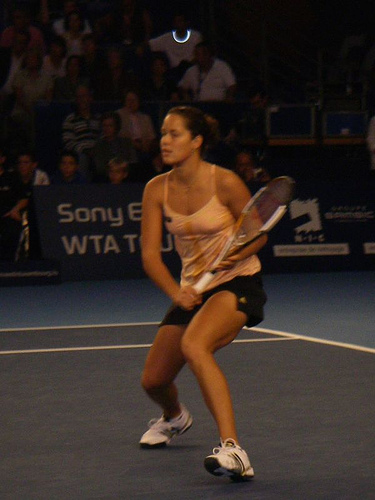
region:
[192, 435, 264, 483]
white shoe on tennis player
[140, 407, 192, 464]
white shoe on tennis player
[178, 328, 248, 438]
left leg of tennis player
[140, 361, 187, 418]
right leg of tennis player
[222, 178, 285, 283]
tennis racquet in player's hand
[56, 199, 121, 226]
sony advertisement on wall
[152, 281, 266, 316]
black tennis skirt on woman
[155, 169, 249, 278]
peach tank top on woman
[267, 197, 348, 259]
logo of sponsor on wall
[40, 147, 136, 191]
spectators in stand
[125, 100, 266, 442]
this is a tennis player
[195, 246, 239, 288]
she is holding a racket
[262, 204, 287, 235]
the racket is white in color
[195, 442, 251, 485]
the leg is raised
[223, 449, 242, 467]
the shoe is white in color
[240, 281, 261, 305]
the skirt is black in color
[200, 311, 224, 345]
this is the thigh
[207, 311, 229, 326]
the player is light skinned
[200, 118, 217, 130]
the hair is short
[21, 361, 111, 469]
the pitch is tarmacked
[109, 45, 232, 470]
a woman playing tennis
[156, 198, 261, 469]
a woman playing tennis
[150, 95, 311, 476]
a woman playing tennis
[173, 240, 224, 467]
a woman playing tennis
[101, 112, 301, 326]
woman playing a game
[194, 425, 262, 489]
shoe of the lady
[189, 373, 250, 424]
leg of the lady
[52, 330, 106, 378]
white line on court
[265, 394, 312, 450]
dark blue court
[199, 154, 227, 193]
strap on the woman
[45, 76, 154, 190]
people in the background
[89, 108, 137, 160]
woman in the background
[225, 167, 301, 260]
racket in woman's hand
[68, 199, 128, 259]
white words on the sign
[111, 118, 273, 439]
a woman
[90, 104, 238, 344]
a woman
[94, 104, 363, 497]
a woman